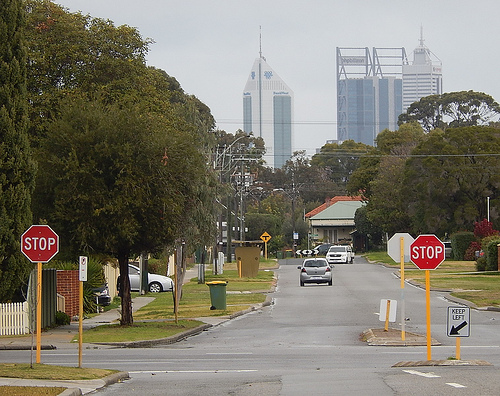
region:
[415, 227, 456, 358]
stop sign on a street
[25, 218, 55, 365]
stop sign on a side walk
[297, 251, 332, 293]
gray car driving down a street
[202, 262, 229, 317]
trash can on the side of a street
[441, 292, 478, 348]
street sign on the side of street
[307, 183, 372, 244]
house on the side of street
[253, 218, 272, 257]
traffic sign on the side of a street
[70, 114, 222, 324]
big green tree on the side of street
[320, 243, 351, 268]
van driving down a street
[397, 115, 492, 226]
tree on the side of street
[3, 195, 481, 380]
two red stop signs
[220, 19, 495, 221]
tall buildings in the background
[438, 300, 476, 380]
black and white rectangular sign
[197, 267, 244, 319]
green and yellow trash bin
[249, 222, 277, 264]
yellow and black sign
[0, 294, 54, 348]
white picket fence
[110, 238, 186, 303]
white car in driveway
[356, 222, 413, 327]
road signs facing opposite the camera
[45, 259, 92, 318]
brick fence under tall trees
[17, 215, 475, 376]
street signs on yellow poles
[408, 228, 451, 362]
stop sign on yellow pole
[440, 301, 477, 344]
white sign with arrow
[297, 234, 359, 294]
two cars in street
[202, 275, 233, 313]
yellow trash can in street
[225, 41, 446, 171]
skyscrapers on horizon behind trees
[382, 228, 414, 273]
back of stop sign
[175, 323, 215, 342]
curb on side of street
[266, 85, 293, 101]
word on side of building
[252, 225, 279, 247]
yellow sign with black symbol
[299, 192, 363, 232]
roofs of two buildings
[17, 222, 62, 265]
Stop sign on the left side of the road.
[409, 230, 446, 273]
Stop sign on the right side of the road.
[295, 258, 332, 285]
The back end of a silver vehicle driving away.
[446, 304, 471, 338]
A white and black sign that says Keep Left.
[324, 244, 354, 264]
A white van driving down the road.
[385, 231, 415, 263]
The back of a stop sign.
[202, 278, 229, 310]
A green trashcan with a yellow lid.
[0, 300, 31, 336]
White picket fence to the left of a stop sign.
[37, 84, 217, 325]
Tall green tree behind a stop sign on the left.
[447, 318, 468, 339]
Large black arrow pointing to the left.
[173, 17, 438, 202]
Skyscrapers in the background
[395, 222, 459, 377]
A stop sign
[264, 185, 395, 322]
Cars driving down the road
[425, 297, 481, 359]
A sign saying to "keep left"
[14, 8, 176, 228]
Many trees on the side of the road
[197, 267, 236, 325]
A garbage can sits at the curb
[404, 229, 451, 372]
The stop sign is red and yellow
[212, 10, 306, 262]
The building is white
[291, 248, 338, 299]
The car is grey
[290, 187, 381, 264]
A building ahead